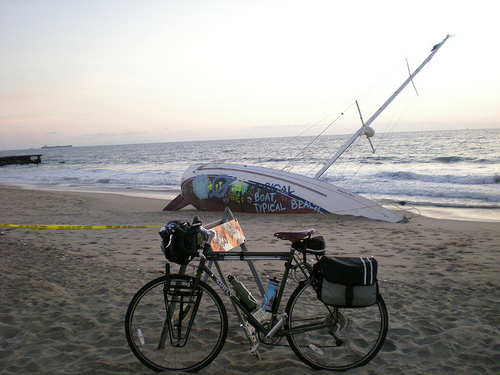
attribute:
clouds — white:
[445, 12, 495, 35]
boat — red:
[169, 157, 378, 217]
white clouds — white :
[64, 68, 102, 106]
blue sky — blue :
[4, 4, 499, 196]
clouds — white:
[110, 27, 346, 101]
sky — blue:
[2, 6, 487, 157]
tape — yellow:
[33, 211, 122, 242]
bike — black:
[123, 215, 393, 372]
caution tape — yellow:
[3, 218, 153, 235]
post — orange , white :
[168, 207, 284, 356]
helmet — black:
[152, 219, 198, 266]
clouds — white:
[134, 38, 272, 99]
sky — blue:
[0, 0, 497, 129]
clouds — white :
[38, 72, 133, 101]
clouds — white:
[7, 102, 191, 144]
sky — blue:
[423, 87, 497, 129]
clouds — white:
[174, 29, 432, 120]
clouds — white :
[1, 121, 176, 142]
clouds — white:
[122, 27, 207, 67]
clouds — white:
[143, 13, 499, 113]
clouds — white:
[305, 36, 357, 53]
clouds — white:
[470, 97, 487, 119]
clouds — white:
[35, 57, 71, 92]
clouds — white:
[110, 41, 183, 85]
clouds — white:
[446, 78, 468, 112]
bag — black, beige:
[318, 259, 388, 306]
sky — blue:
[8, 9, 481, 144]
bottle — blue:
[264, 270, 286, 320]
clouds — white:
[1, 0, 498, 147]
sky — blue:
[0, 0, 500, 151]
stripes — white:
[359, 254, 375, 284]